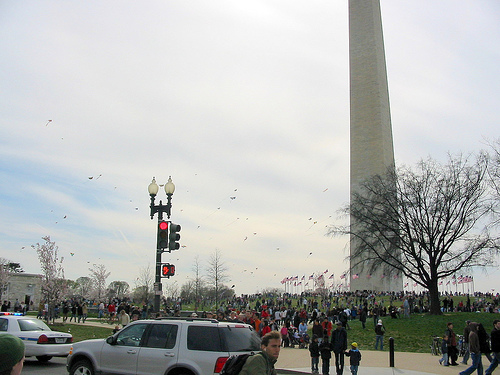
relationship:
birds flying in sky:
[216, 179, 252, 227] [8, 164, 96, 233]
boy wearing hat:
[342, 340, 368, 372] [351, 342, 358, 348]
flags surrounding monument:
[274, 269, 480, 291] [345, 1, 413, 296]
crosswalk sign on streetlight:
[161, 257, 175, 282] [142, 174, 174, 314]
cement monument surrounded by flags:
[346, 0, 405, 293] [278, 269, 476, 294]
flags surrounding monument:
[280, 269, 475, 298] [334, 50, 401, 177]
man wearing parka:
[219, 330, 282, 375] [234, 352, 276, 372]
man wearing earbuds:
[219, 330, 282, 375] [262, 346, 274, 361]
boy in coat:
[343, 342, 362, 375] [343, 349, 363, 365]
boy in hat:
[343, 342, 362, 375] [348, 339, 359, 349]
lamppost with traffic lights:
[142, 179, 177, 311] [157, 218, 182, 253]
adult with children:
[331, 320, 350, 372] [309, 314, 366, 374]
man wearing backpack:
[234, 322, 297, 367] [217, 352, 250, 372]